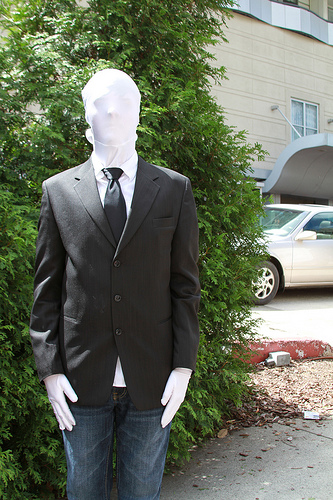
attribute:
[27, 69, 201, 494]
man — standing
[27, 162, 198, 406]
suit — black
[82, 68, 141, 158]
mask — white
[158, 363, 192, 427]
glove — white, covering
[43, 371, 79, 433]
glove — white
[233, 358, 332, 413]
chips — wood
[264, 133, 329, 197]
awning — metal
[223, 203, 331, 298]
car — silver, parked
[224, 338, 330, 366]
curb — red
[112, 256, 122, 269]
button — round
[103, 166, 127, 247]
tie — black, shiny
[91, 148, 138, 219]
shirt — white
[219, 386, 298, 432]
leaves — brown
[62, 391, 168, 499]
jeans — blue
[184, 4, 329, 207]
building — concrete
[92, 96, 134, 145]
face — covered